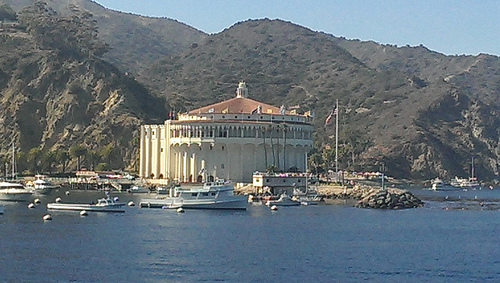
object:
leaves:
[23, 148, 40, 164]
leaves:
[51, 145, 73, 165]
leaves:
[68, 142, 89, 157]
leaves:
[104, 144, 121, 161]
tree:
[310, 151, 323, 186]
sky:
[173, 0, 500, 90]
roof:
[164, 79, 314, 125]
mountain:
[0, 0, 500, 185]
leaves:
[41, 149, 61, 164]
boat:
[267, 193, 301, 206]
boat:
[139, 183, 248, 210]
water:
[0, 182, 500, 283]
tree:
[84, 148, 99, 171]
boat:
[46, 202, 128, 213]